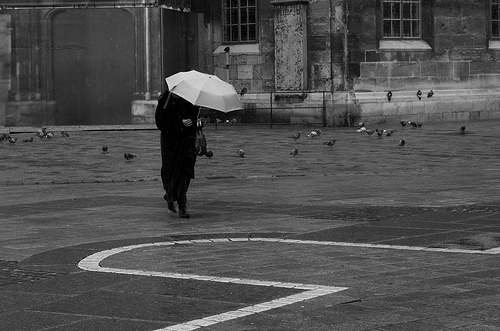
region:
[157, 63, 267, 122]
person holding a white umbrella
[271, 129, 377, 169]
pigeons on the ground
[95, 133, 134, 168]
pigeons on the ground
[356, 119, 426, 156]
pigeons on the ground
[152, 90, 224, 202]
Person wearing a black jacket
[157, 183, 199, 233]
person wearing black boots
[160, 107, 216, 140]
person holding a umbrella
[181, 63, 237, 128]
white umbrella in the rain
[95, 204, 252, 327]
white lines on the ground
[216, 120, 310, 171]
pigeons next to each other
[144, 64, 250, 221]
a person with a umbrella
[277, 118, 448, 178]
birds on the brick court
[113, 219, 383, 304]
white bricks on the court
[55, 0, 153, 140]
a metal door on the wall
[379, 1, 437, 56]
a window in the build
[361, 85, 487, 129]
stones on the bottom of the building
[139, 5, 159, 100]
a gray pip on the wall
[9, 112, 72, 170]
a group of birds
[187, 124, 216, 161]
a small bag under arm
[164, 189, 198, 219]
black boots on feet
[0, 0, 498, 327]
the photo is in black and white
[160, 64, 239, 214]
the person holds and umbrella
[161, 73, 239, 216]
the umbrella is white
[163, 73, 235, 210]
the person is dressed in black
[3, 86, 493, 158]
man birds on ground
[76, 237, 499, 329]
a white line on ground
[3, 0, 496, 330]
the day is raining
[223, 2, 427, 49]
the building has windows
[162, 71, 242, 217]
the person is walking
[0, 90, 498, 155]
the birds are black and white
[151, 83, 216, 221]
person dressed in all black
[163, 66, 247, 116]
light colored umbrella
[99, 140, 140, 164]
two dark pigeons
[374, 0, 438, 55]
window set into the stone wall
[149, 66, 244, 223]
a person walking while holding an umbrella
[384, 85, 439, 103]
three pigeons perched on a ledge at the bottom of a wall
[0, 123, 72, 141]
a cluster of several pigeons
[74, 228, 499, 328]
a white line set into the road with stones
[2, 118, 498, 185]
a cobblestone road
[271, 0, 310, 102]
a concrete pillar covered with moss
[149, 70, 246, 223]
Person with an umbrella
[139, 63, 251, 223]
Person walking in the rain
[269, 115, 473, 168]
Pigeons gathered in a square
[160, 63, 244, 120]
Umbrella opened in the rain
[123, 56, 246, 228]
Woman trying to avoid getting wet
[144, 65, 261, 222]
Person trying to avoid bird poop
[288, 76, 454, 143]
pigeons begging for food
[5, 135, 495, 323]
Square full of pigeons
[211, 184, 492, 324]
Wet cement walk way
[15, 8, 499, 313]
Dreary rainy day walk